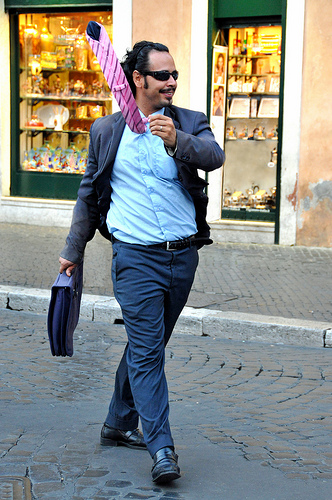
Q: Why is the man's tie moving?
A: The wind is blowing.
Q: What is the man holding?
A: A briefcase.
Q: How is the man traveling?
A: Walking.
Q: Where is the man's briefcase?
A: In his hand.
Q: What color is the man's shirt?
A: Blue.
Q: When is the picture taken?
A: Daytime.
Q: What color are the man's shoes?
A: Black.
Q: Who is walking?
A: A man.